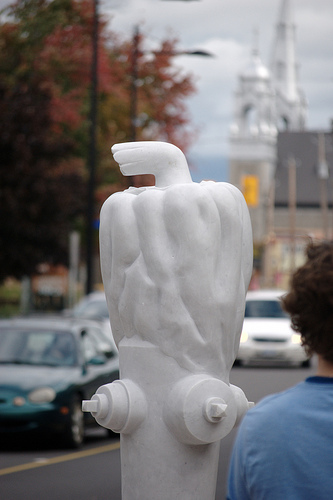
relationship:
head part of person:
[277, 235, 331, 365] [219, 239, 330, 498]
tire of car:
[57, 391, 96, 445] [3, 312, 119, 449]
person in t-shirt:
[219, 239, 330, 498] [222, 370, 332, 499]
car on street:
[0, 318, 120, 445] [3, 455, 106, 499]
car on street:
[231, 289, 311, 370] [1, 349, 320, 497]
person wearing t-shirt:
[219, 239, 330, 498] [222, 370, 332, 499]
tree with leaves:
[13, 7, 80, 251] [21, 38, 97, 79]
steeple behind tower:
[273, 4, 306, 128] [227, 28, 279, 281]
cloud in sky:
[177, 36, 268, 92] [0, 0, 333, 186]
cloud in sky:
[141, 0, 332, 120] [0, 0, 333, 186]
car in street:
[0, 318, 120, 445] [2, 363, 321, 496]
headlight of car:
[26, 384, 56, 403] [3, 312, 119, 449]